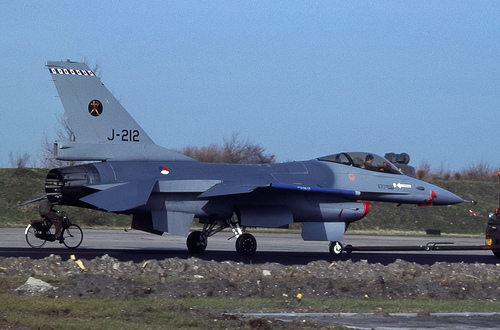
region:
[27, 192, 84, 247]
A person on a bicycle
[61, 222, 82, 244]
The front tire of the bicycle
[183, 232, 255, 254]
Wheels on the jet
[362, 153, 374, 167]
A person sitting in the jet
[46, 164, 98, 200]
The engine of the jet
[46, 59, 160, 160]
The tail of the jet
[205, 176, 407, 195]
The wing of the jet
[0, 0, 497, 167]
The sky above the jet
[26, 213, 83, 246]
A bicycle near the jet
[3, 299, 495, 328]
Grass next to the jet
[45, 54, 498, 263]
A fighter jet in transit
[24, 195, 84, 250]
A cyclist gaining on the jet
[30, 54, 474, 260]
A gray fighter jet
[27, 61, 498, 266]
The dark car with a jet trailer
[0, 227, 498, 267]
A smooth tarmacked road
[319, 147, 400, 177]
The fighter jet cockpit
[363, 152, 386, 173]
The fighter jet pilot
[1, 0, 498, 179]
A clear blue sky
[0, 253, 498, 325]
A dirt filled side space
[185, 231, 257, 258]
The two dark fighter jet wheels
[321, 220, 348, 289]
part of a wheel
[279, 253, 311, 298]
part of a ground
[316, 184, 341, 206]
edge of a wing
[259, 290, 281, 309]
part of a ground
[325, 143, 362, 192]
part of a plane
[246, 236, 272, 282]
par tof a wing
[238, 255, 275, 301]
part of a ground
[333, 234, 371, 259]
part of a wheel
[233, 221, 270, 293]
par tof a rim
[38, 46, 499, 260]
fighter jet on the runway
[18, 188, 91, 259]
person riding a bike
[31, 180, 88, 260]
person on the bike near a fighter jet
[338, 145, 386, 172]
pilot in the cockpit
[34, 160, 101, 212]
engine on a plane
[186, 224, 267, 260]
wheels on a fighter jet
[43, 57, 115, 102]
tail of the jet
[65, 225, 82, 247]
front tire of the bike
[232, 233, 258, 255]
wheel of the jet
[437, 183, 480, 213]
nose of the jet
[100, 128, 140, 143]
a number and letters on the jet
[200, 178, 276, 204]
the jets wing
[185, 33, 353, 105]
the sky is clear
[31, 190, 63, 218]
a person riding a bike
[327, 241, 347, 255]
the front wheel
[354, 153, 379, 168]
a person in the jet